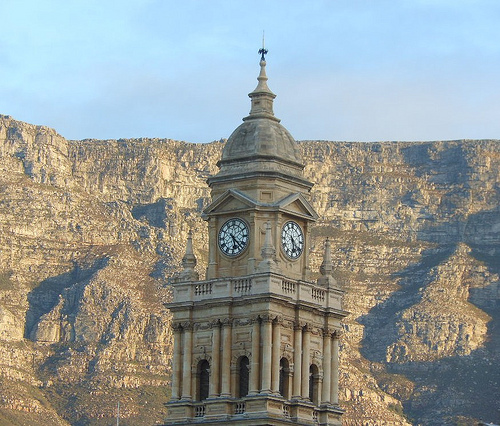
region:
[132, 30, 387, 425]
a building with a clock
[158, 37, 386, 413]
building with a clock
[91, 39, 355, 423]
building with two clocks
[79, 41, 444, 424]
building by mountains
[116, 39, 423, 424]
building during the day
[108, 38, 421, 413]
building in the sunlight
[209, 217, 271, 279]
a medium white clock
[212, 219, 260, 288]
a clock with black arms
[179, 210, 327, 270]
two medium white clocks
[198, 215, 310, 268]
two clocks with black arms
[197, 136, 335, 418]
Tower is brown color.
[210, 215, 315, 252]
Two clock face is seen.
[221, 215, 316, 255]
Clock is black and white color.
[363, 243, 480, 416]
Mountain is brown color.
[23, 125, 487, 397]
Mountain is behind the clock.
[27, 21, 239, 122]
Sky is blue color.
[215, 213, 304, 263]
5.23 is the time shown.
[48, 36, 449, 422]
Day time pictures.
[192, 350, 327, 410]
Windows are attached to the tower.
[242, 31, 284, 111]
Tower tip is pointed.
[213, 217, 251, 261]
a white clock on the tower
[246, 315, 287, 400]
a brown pillar on the building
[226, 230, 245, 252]
the hands of a clock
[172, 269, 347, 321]
a railing on a building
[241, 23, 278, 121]
the tip of a tower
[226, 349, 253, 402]
the window on a building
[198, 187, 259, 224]
a triangle over the clock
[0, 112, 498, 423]
a brown cliff face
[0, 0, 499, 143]
a clear blue sky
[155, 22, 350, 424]
a brown building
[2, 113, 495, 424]
rock cliff walls behind a building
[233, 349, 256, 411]
an arched opening in a clock tower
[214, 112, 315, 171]
the dome on a clock tower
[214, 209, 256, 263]
one face of a clock tower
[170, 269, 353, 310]
a parpet around a clock tower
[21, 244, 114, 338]
a shadow on the cliff face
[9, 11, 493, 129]
a pale blue sky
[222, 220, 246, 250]
Roman numerals on a clock face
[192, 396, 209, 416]
a railing at an arched opening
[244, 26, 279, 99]
the spire of a clock tower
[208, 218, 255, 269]
a white clock face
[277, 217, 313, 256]
the second clock face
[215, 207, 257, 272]
the first clock face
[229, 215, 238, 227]
the roman number 12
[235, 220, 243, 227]
the roman number 1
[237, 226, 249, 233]
the roman number 2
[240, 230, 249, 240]
the roman number 3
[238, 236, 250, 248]
the roman number 4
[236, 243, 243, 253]
the roman number 5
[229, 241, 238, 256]
the roman number 6